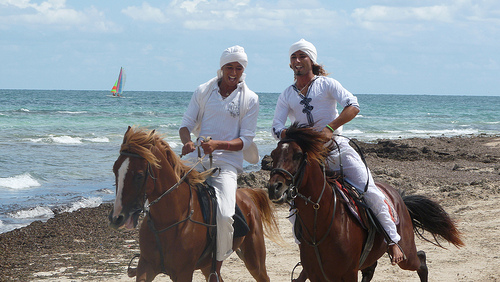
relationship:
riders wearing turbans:
[206, 36, 357, 177] [218, 39, 320, 60]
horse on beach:
[109, 140, 209, 281] [433, 165, 497, 206]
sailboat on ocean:
[113, 66, 133, 99] [49, 97, 120, 131]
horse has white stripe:
[109, 140, 209, 281] [110, 156, 133, 220]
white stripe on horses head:
[110, 156, 133, 220] [108, 138, 166, 229]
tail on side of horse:
[405, 191, 466, 249] [274, 136, 364, 281]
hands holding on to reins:
[182, 140, 217, 156] [178, 142, 206, 177]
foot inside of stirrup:
[392, 242, 403, 263] [386, 237, 405, 266]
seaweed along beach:
[5, 203, 46, 213] [0, 132, 500, 281]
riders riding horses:
[206, 36, 357, 177] [121, 135, 341, 234]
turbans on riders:
[218, 39, 320, 60] [206, 36, 357, 177]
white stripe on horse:
[110, 156, 133, 220] [109, 140, 209, 281]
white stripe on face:
[110, 156, 133, 220] [104, 148, 150, 230]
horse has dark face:
[274, 136, 364, 281] [268, 139, 315, 203]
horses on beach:
[121, 135, 341, 234] [433, 165, 497, 206]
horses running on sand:
[121, 135, 341, 234] [272, 253, 289, 280]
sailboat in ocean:
[113, 66, 133, 99] [49, 97, 120, 131]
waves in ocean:
[37, 130, 97, 147] [49, 97, 120, 131]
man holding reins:
[187, 49, 253, 228] [178, 142, 206, 177]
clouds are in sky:
[183, 14, 245, 31] [55, 13, 235, 45]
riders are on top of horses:
[206, 36, 357, 177] [121, 135, 341, 234]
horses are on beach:
[121, 135, 341, 234] [433, 165, 497, 206]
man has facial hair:
[286, 44, 351, 174] [296, 68, 304, 77]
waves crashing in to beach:
[37, 130, 97, 147] [433, 165, 497, 206]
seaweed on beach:
[5, 203, 46, 213] [433, 165, 497, 206]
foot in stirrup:
[392, 242, 403, 263] [386, 237, 405, 266]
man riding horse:
[187, 49, 253, 228] [109, 140, 209, 281]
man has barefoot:
[286, 44, 351, 174] [392, 242, 403, 263]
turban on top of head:
[218, 45, 249, 68] [217, 45, 252, 92]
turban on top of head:
[292, 40, 317, 52] [289, 44, 320, 76]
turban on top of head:
[225, 45, 246, 62] [217, 45, 252, 92]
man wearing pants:
[187, 49, 253, 228] [216, 164, 239, 241]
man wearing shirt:
[187, 49, 253, 228] [201, 81, 258, 149]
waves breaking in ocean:
[37, 130, 97, 147] [49, 97, 120, 131]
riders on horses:
[206, 36, 357, 177] [121, 135, 341, 234]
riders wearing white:
[206, 36, 357, 177] [242, 96, 297, 131]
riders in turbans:
[206, 36, 357, 177] [218, 39, 320, 60]